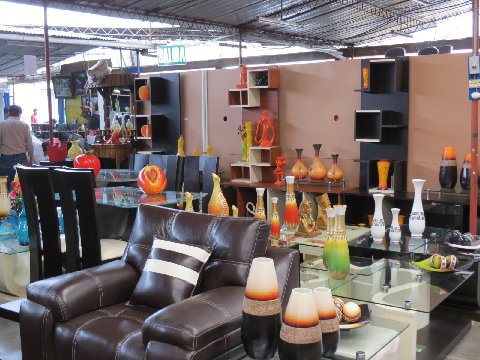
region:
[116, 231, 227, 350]
a brown and white pillow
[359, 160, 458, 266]
three white vases with gray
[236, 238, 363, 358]
three brown white and orange vases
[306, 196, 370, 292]
two green and yellow vases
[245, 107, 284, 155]
a wierd shaped orange object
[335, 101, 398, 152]
an empty black box on wall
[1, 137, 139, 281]
two black and white chairs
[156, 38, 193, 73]
a green and white sign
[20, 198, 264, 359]
a brown leather chair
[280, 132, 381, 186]
three orange and brown vases by wall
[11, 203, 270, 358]
brown leather recliner chair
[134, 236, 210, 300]
brown and white pillow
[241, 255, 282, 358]
white orange black and brown candle holder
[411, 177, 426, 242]
white vase on table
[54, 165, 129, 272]
black and white dining chair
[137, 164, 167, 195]
orange sculpture on table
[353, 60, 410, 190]
black shelf on wall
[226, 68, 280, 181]
white and pink shelf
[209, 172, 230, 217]
yellow and orange vase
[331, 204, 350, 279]
green yellow and tan case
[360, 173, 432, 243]
three white vases on table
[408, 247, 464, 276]
interior design green bowl on table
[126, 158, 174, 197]
orange vase on table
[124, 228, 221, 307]
brown leather throw pillow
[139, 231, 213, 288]
white stripe on leather pillow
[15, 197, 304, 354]
brown leather arm chair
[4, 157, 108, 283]
brown table chair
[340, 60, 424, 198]
brown wall shelves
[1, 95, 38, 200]
person walking through shop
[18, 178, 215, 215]
rectangular glass table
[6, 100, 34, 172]
man in white shirt on far left of picture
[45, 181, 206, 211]
glass topped table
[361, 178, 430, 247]
set of white vases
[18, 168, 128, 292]
black dining chair with white seat cushion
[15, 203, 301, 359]
large black leather chair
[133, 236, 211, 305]
black leather pillow with white stripes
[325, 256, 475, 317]
glass coffee table with white base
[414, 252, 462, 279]
green dish with decorative balls in it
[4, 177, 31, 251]
pink flowers in blue vase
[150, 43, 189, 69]
green and white sign hanging from rafters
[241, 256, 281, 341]
a smal pieces of light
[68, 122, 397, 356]
a group of objects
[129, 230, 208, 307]
a small pillow on chair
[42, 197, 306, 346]
a big tight chair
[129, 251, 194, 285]
a white line in chair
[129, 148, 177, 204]
a flower on table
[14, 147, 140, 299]
a beautiful wooden chair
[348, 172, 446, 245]
a beautiful view of glasses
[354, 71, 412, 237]
a long door in wall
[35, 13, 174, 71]
light falling in top